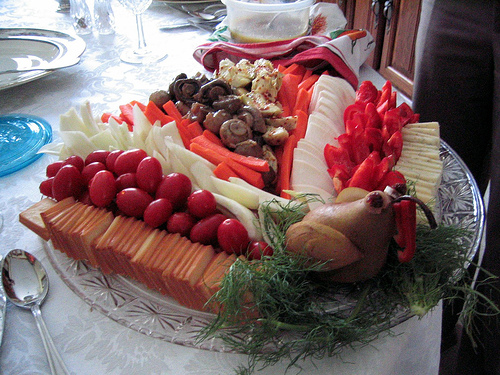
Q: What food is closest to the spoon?
A: Sliced cheese is near the spoon.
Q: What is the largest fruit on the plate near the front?
A: There is a pear near the front of the plate.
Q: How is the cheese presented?
A: The cheese is sliced.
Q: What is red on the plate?
A: Red peppers.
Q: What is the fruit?
A: Pear.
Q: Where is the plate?
A: On the table.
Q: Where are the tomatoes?
A: Beside the cheese.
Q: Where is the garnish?
A: On the edge.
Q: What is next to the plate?
A: A spoon is next to the plate.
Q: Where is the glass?
A: On the countertop.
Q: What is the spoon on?
A: A cloth.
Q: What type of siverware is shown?
A: A spoon.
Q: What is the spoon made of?
A: Metal.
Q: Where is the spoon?
A: In the bottom, left-hand corner.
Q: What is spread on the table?
A: Tablecloth.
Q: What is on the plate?
A: Food items.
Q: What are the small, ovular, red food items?
A: Grape tomatoes.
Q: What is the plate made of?
A: Glass.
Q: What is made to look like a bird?
A: A pear.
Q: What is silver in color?
A: The spoon.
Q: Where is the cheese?
A: On the plate.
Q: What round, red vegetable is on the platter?
A: Tomatoes.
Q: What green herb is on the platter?
A: Fresh dill.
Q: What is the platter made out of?
A: Glass.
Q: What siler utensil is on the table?
A: A spoon.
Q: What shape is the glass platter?
A: Round.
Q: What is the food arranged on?
A: A glass platter.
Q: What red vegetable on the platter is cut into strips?
A: Red pepper.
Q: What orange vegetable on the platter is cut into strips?
A: Carrot.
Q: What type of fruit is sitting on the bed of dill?
A: A pear.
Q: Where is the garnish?
A: On the platter.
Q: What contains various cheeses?
A: The serving platter.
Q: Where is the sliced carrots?
A: Snack tray.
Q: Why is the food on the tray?
A: To be served.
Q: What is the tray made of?
A: Glass.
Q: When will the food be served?
A: When it is time.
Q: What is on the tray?
A: Food.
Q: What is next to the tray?
A: A spoon.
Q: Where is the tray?
A: On the table.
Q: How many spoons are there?
A: One.